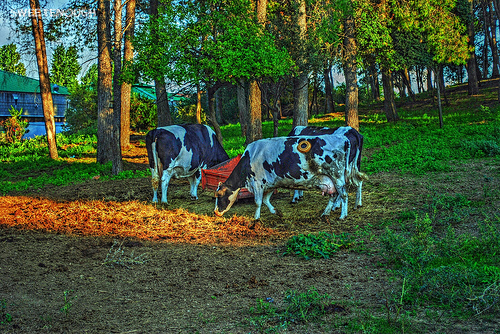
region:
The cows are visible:
[168, 81, 365, 300]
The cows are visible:
[147, 38, 392, 220]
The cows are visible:
[153, 88, 343, 189]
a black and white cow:
[202, 126, 359, 227]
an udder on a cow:
[310, 171, 346, 197]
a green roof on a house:
[2, 68, 71, 98]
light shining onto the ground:
[2, 187, 277, 243]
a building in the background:
[0, 65, 69, 149]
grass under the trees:
[215, 87, 496, 173]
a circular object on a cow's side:
[293, 137, 313, 153]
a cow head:
[209, 181, 243, 219]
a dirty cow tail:
[149, 134, 162, 194]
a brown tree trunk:
[342, 47, 360, 130]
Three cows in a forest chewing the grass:
[135, 105, 380, 239]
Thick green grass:
[383, 113, 474, 168]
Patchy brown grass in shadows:
[28, 244, 221, 316]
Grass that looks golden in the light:
[22, 202, 165, 238]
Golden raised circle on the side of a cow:
[292, 137, 317, 152]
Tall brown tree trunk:
[85, 0, 129, 169]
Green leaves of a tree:
[129, 11, 292, 83]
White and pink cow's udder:
[314, 174, 338, 198]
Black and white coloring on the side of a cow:
[148, 128, 204, 160]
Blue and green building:
[0, 60, 72, 133]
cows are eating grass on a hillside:
[5, 2, 498, 324]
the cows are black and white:
[132, 109, 370, 231]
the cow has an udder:
[309, 175, 341, 201]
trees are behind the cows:
[30, 17, 499, 182]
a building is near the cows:
[0, 66, 71, 153]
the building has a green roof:
[2, 69, 68, 97]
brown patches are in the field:
[8, 162, 498, 325]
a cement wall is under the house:
[3, 120, 66, 145]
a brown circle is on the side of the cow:
[293, 137, 315, 155]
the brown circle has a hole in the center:
[295, 138, 313, 152]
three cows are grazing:
[142, 108, 374, 223]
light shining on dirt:
[8, 188, 274, 256]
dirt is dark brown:
[15, 226, 359, 331]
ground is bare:
[9, 177, 413, 332]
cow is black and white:
[217, 122, 353, 214]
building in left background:
[0, 72, 94, 154]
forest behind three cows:
[35, 0, 497, 110]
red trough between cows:
[189, 155, 257, 187]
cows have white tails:
[146, 141, 169, 196]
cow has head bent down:
[208, 132, 367, 218]